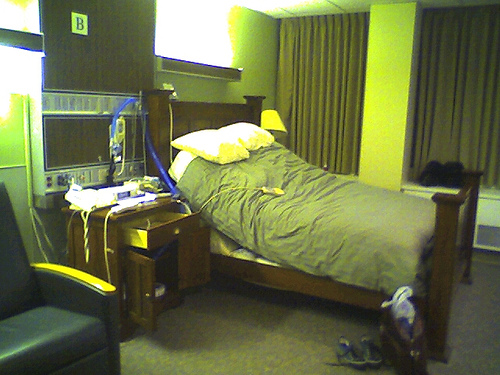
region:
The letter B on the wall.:
[69, 16, 89, 31]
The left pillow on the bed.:
[165, 126, 251, 173]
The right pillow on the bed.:
[219, 117, 272, 152]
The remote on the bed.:
[226, 171, 301, 201]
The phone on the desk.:
[62, 181, 115, 215]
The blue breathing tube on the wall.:
[112, 85, 184, 180]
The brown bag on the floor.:
[383, 285, 433, 373]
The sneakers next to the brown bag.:
[322, 327, 388, 372]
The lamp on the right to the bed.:
[260, 106, 290, 149]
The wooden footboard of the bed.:
[437, 146, 489, 345]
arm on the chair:
[26, 258, 123, 304]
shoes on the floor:
[328, 331, 383, 366]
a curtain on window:
[430, 20, 487, 102]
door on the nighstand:
[128, 254, 162, 324]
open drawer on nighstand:
[130, 210, 200, 237]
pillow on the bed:
[188, 132, 256, 153]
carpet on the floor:
[168, 335, 257, 365]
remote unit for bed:
[250, 182, 300, 205]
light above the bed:
[162, 51, 255, 81]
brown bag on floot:
[374, 294, 437, 368]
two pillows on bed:
[168, 106, 276, 161]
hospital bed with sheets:
[157, 106, 479, 309]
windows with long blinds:
[275, 15, 498, 187]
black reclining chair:
[0, 178, 130, 369]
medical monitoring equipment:
[40, 88, 197, 213]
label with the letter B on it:
[70, 11, 93, 41]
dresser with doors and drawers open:
[68, 203, 220, 337]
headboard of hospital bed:
[154, 86, 287, 300]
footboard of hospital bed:
[431, 155, 485, 354]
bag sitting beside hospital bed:
[377, 283, 444, 373]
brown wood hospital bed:
[137, 80, 492, 358]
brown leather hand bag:
[378, 277, 433, 370]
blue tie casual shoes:
[321, 321, 388, 373]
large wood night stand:
[45, 172, 227, 332]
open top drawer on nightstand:
[102, 207, 205, 245]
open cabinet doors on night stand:
[113, 219, 228, 339]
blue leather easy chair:
[3, 174, 129, 374]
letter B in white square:
[65, 10, 95, 47]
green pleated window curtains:
[265, 0, 498, 192]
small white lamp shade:
[253, 97, 286, 144]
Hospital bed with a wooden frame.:
[145, 88, 485, 363]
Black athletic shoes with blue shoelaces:
[323, 333, 384, 373]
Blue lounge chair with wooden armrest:
[0, 179, 125, 373]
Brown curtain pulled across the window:
[269, 6, 371, 178]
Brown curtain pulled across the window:
[402, 3, 498, 203]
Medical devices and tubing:
[105, 82, 190, 211]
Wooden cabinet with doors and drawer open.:
[62, 193, 213, 347]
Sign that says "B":
[69, 8, 91, 35]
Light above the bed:
[154, 37, 246, 84]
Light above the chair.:
[0, 11, 47, 65]